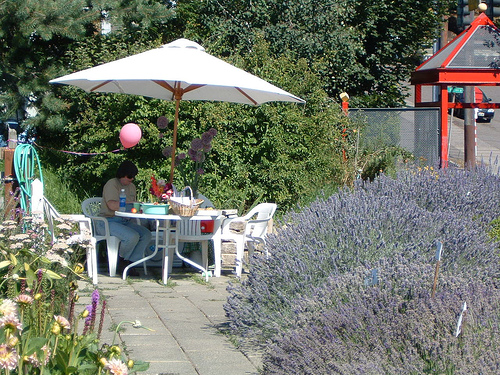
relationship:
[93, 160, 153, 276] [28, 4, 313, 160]
woman sitting under umbrella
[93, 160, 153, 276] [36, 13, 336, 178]
woman sitting under umbrella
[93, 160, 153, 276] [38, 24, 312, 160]
woman sitting under umbrella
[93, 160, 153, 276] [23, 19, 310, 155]
woman sitting under umbrella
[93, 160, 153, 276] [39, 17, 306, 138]
woman sitting under umbrella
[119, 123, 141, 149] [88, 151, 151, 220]
balloon above woman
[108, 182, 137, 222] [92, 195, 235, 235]
water on table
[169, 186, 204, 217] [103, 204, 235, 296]
basket on table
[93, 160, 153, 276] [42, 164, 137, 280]
woman sitting in chair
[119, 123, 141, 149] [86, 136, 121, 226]
balloon on string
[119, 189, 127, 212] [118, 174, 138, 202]
bottle with label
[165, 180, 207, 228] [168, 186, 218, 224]
basket with handle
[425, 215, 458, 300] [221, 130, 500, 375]
paper sign in bush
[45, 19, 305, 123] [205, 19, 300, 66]
umbrella blocking sun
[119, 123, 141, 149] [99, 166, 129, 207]
balloon above head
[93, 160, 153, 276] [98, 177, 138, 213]
woman sitting shirt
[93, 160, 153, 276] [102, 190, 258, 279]
woman sitting table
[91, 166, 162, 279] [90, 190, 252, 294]
woman sitting table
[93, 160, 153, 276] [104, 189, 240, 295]
woman sitting table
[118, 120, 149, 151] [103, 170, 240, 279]
balloon floating table